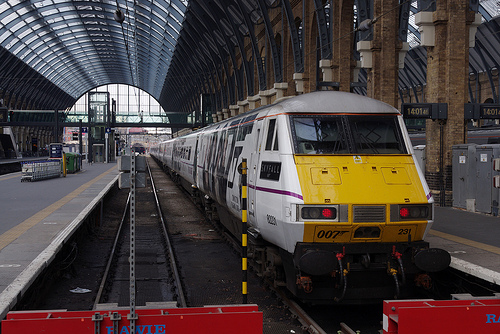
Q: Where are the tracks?
A: The tracks are on the station.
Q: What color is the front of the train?
A: The front of the train is yellow.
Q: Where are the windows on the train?
A: The windows are in the front of the train.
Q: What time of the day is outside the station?
A: The station is daylight time.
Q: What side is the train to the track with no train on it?
A: The train is on the right of the empty tracks.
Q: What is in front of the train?
A: There are red bumpers in front of the train.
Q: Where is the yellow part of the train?
A: Front.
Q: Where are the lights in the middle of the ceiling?
A: Top.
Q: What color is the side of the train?
A: White.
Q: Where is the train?
A: At the train station.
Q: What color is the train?
A: Yellow and White.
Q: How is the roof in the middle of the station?
A: Arched.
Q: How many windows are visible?
A: 2.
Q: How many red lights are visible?
A: 2.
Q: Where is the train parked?
A: Platform.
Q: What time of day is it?
A: Afternoon.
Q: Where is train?
A: In station.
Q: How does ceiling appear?
A: High domed.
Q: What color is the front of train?
A: Yellow.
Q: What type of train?
A: Metro type.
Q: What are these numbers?
A: 007.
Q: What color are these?
A: Red.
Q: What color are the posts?
A: Yellow and black.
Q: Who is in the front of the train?
A: The driver.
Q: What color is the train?
A: White and yellow.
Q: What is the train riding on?
A: Tracks.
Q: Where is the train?
A: In a train station.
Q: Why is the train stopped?
A: Letting passengers on and off.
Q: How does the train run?
A: With the engine in front.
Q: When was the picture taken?
A: Daytime.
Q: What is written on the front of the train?
A: 007.